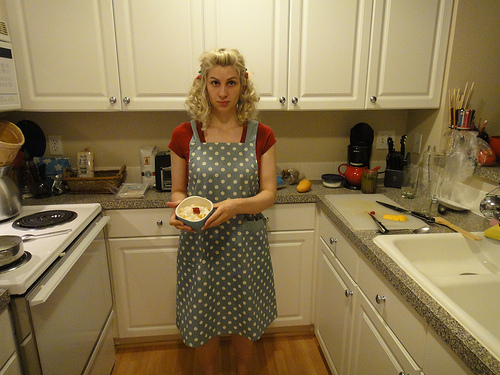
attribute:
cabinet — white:
[365, 0, 464, 113]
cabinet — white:
[287, 0, 372, 110]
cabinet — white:
[205, 0, 292, 114]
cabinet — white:
[116, 0, 202, 107]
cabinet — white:
[6, 1, 120, 108]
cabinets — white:
[1, 0, 455, 100]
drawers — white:
[320, 227, 452, 370]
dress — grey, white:
[150, 105, 294, 344]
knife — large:
[373, 195, 435, 224]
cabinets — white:
[5, 2, 120, 108]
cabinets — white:
[110, 2, 206, 105]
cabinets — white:
[205, 2, 290, 107]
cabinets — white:
[286, 0, 373, 109]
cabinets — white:
[372, 2, 454, 111]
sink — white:
[385, 208, 499, 336]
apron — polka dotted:
[171, 116, 273, 344]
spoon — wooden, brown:
[433, 212, 478, 242]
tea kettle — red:
[330, 155, 377, 193]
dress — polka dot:
[175, 116, 280, 346]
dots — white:
[219, 252, 243, 287]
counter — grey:
[386, 177, 483, 259]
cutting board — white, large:
[328, 190, 425, 237]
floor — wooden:
[110, 323, 323, 373]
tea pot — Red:
[334, 160, 373, 187]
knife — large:
[359, 193, 449, 238]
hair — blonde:
[172, 49, 268, 132]